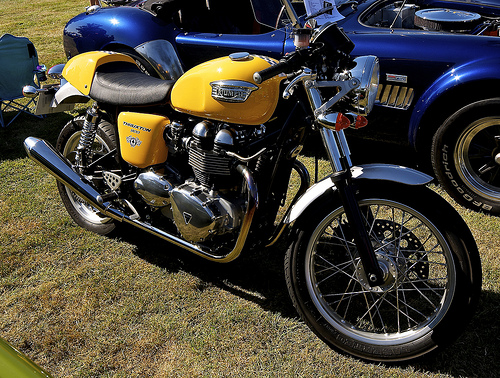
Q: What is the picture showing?
A: A motorcycle.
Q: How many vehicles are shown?
A: Two.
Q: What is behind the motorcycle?
A: A car.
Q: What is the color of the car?
A: Blue.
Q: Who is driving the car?
A: Nobody.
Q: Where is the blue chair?
A: Behind the motorcycle.